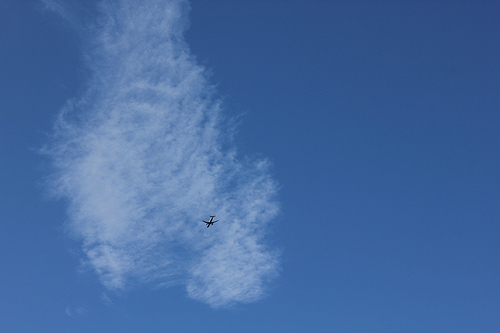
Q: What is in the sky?
A: Plane.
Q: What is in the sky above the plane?
A: Clouds.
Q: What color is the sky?
A: Blue.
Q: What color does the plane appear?
A: Black.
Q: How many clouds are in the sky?
A: 1.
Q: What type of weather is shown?
A: Clear.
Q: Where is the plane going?
A: Down.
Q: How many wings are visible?
A: 2.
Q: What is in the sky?
A: Plane.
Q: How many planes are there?
A: One.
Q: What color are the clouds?
A: White.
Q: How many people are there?
A: None.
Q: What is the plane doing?
A: Flying.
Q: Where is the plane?
A: In the sky.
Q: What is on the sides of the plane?
A: Wings.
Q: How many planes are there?
A: One.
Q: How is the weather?
A: Pleasant.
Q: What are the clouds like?
A: Sparse.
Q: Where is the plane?
A: In the sky.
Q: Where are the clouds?
A: Over the plane.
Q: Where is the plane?
A: In the sky.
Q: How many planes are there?
A: One.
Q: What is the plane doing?
A: Flying.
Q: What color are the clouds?
A: White.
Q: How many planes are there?
A: One.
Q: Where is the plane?
A: In the sky.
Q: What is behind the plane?
A: Cloud.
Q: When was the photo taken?
A: During the day.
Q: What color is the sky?
A: Blue.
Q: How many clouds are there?
A: One stratus.